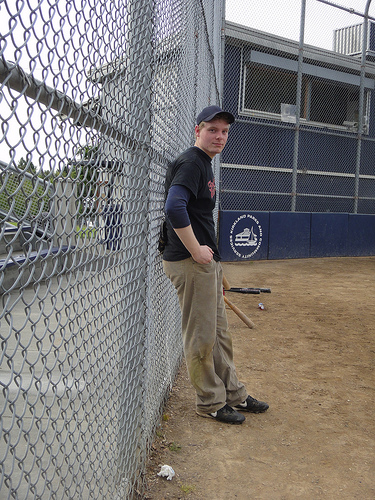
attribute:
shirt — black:
[157, 144, 221, 261]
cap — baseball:
[193, 102, 236, 125]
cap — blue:
[196, 102, 237, 121]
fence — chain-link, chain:
[9, 1, 226, 498]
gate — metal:
[0, 23, 151, 303]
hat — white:
[193, 101, 234, 125]